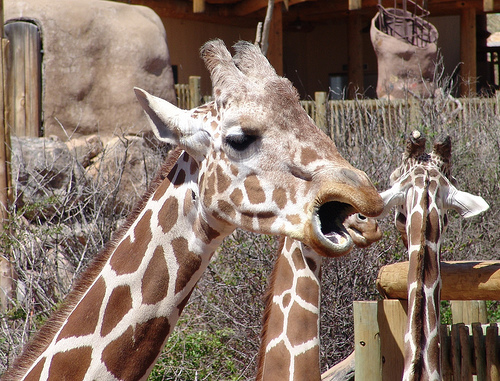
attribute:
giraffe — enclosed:
[3, 40, 383, 374]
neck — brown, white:
[12, 105, 221, 378]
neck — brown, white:
[401, 183, 444, 381]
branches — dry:
[9, 50, 496, 347]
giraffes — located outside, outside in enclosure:
[5, 39, 491, 378]